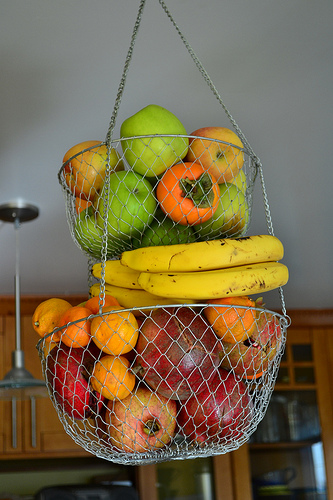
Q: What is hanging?
A: Basket.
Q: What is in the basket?
A: Fruits.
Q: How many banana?
A: 4.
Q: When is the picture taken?
A: Daytime.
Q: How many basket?
A: 2.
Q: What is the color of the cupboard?
A: Brown.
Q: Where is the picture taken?
A: In a kitchen.